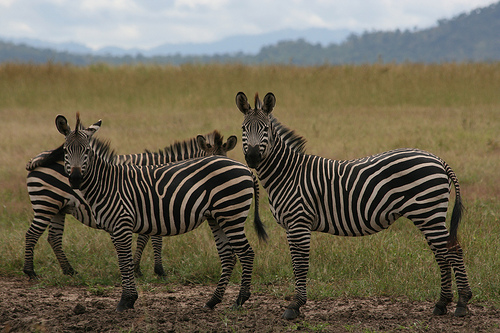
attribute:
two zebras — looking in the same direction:
[20, 106, 269, 318]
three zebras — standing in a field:
[18, 90, 475, 331]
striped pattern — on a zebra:
[307, 165, 408, 220]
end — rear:
[408, 140, 469, 240]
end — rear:
[195, 140, 270, 250]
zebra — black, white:
[56, 110, 259, 312]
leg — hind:
[220, 218, 265, 309]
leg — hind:
[205, 214, 237, 308]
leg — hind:
[444, 224, 474, 320]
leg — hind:
[415, 224, 461, 312]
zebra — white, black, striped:
[233, 97, 482, 324]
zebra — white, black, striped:
[19, 132, 249, 288]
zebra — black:
[224, 88, 469, 311]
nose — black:
[237, 146, 262, 164]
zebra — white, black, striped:
[50, 117, 275, 322]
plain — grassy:
[4, 64, 493, 331]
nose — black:
[240, 139, 272, 186]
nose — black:
[67, 163, 85, 195]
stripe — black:
[146, 169, 206, 239]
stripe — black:
[167, 165, 217, 254]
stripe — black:
[136, 173, 166, 229]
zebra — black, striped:
[201, 85, 475, 327]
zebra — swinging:
[55, 129, 321, 324]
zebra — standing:
[26, 101, 439, 300]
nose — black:
[57, 144, 106, 204]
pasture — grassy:
[32, 44, 497, 117]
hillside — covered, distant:
[176, 13, 483, 78]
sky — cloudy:
[103, 10, 249, 42]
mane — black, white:
[92, 111, 165, 163]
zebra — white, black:
[59, 128, 255, 302]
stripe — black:
[347, 160, 396, 220]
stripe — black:
[351, 161, 431, 209]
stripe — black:
[164, 160, 225, 215]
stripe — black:
[146, 171, 167, 224]